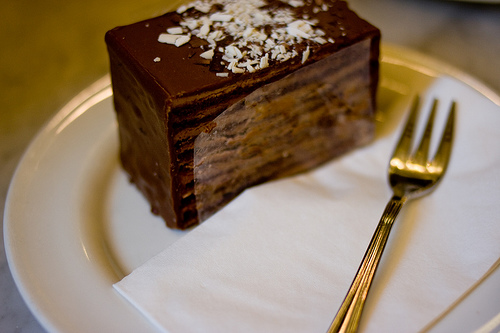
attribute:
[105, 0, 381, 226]
cake — multi layered, chocolate, square shaped, layered, small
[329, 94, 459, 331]
fork — silver, three-pronged, out of focus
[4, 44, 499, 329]
plate — white, round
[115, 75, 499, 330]
napkin — white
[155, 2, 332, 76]
sprinkles — white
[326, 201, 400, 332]
handle of fork — metal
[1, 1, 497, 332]
table — blurry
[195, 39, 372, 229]
paper — think